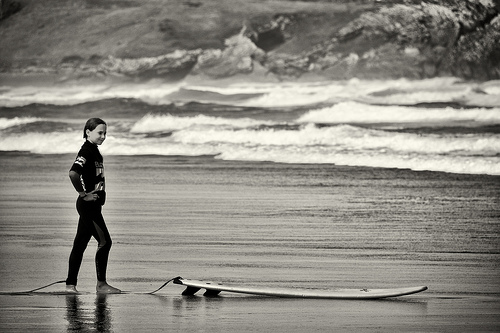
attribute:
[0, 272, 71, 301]
string — white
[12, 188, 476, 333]
sand — wet, sandy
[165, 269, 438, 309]
surfboard — white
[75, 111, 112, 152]
black hair — wet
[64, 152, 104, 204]
right hand — bend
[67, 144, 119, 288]
wetsuit — black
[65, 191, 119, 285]
pants — black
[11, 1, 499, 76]
wave — large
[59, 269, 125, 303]
feet — wet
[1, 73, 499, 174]
surf — white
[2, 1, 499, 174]
sea — choppy, not calm